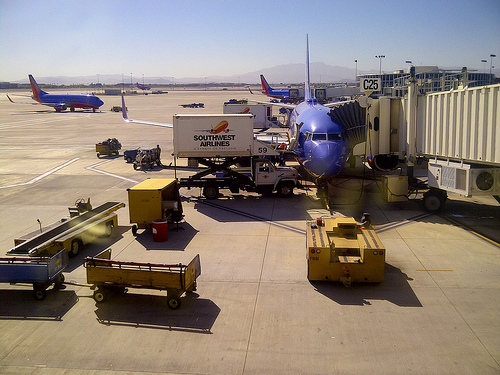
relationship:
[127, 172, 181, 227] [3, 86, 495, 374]
cart in pavement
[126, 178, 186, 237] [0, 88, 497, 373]
cart on tarp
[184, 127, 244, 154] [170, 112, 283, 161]
airline on truck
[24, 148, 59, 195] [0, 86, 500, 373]
line on pavement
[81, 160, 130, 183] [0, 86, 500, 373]
line on pavement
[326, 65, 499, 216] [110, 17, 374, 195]
bridge leads to plane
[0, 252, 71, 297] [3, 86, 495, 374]
cart on pavement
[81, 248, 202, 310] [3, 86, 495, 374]
cart on pavement